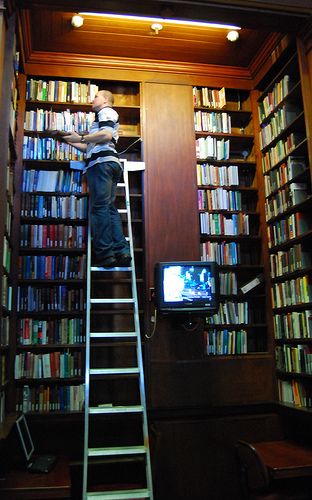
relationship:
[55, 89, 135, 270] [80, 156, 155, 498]
man on top of ladder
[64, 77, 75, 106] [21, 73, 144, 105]
book on book shelf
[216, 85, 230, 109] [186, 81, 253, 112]
book on book shelf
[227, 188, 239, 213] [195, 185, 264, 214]
book on book shelf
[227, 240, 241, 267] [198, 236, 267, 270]
book on book shelf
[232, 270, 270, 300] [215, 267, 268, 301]
book on book shelf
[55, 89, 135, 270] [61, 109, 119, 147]
man has left arm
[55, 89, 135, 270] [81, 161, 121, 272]
man has leg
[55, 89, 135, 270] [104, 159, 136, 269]
man has leg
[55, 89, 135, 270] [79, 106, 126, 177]
man has shirt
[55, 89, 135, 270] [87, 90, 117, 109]
man has head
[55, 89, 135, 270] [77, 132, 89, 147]
man has watch on left wrist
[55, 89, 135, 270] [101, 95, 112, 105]
man has left ear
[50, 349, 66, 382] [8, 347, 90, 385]
book on bookshelf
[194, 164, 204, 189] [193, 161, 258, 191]
book on bookshelf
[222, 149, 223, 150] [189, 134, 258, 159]
book on bookshelf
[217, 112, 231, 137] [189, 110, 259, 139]
book on bookshelf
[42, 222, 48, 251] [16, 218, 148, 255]
book on bookshelf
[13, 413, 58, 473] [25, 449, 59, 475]
computer next to keyboard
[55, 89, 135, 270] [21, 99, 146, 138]
guy puts book on shelf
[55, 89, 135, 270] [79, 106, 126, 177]
guy wearing shirt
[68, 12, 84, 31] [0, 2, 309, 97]
light on ceiling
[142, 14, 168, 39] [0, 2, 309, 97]
light on ceiling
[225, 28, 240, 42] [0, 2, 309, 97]
light on ceiling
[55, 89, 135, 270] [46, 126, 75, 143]
man holding book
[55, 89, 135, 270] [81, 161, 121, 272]
man wearing jeans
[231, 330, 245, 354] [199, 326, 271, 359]
book on top of shelf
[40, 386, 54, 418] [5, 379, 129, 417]
book on top of shelf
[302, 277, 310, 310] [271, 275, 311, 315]
book on top of shelf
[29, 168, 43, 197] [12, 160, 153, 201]
book on top of shelf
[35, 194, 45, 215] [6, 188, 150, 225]
book on top of shelf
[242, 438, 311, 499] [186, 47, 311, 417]
desk below shelves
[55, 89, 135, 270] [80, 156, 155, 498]
man stands on top of ladder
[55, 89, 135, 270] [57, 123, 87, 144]
man holds book in his hand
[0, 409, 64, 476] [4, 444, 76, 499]
computer on top of table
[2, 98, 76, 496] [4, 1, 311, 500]
table on side of library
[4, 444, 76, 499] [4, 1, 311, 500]
table on side of library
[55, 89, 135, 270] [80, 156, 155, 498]
man at top of ladder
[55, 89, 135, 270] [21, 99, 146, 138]
man reaching for bookshelf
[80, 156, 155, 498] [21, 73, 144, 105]
ladder next to book shelf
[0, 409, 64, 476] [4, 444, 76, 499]
computer on top of desk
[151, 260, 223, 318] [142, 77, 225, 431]
tv on side of wall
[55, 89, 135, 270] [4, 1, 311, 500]
man in library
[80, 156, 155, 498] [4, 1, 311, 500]
ladder inside library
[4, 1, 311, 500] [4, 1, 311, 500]
shelves of library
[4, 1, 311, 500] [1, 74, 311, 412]
shelves full of book